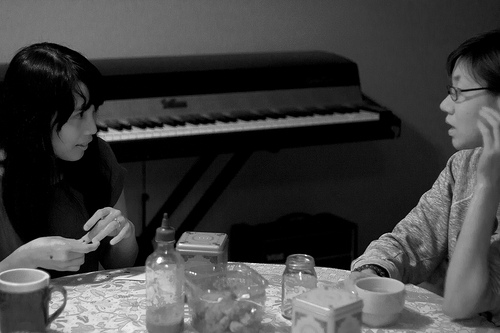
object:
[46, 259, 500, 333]
table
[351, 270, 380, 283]
hand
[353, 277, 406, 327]
cup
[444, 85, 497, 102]
glasses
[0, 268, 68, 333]
mug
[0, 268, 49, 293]
border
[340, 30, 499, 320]
lady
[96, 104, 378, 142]
key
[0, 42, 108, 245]
hair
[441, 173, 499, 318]
arm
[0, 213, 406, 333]
cups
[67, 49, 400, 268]
piano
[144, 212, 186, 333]
bottle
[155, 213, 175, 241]
teat pipette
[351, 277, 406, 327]
whitecup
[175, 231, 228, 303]
boxes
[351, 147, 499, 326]
sweater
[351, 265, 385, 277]
beads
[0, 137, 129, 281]
dark outfit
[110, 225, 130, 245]
fingers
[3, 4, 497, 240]
wall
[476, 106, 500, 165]
hand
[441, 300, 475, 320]
elbow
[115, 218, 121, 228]
ring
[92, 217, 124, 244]
finger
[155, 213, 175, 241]
cap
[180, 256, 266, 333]
bag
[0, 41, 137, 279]
girl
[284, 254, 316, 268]
edge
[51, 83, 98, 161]
face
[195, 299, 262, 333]
fruit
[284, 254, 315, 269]
lid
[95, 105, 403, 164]
board